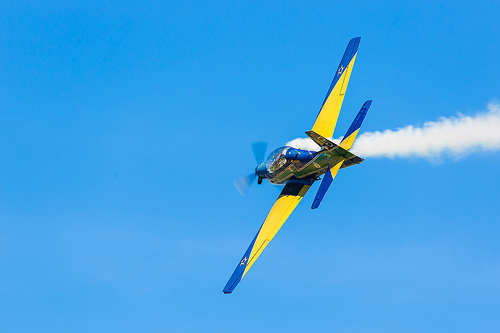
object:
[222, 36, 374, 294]
plane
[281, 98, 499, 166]
smoke trail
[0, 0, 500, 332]
sky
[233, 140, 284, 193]
propeller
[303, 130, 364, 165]
tail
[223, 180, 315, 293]
wing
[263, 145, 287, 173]
windshield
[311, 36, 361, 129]
blue paint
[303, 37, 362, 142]
wing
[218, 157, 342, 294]
left side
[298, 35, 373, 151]
right side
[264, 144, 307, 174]
cockpit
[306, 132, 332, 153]
logo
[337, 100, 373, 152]
tail wing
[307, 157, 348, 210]
hind left wing